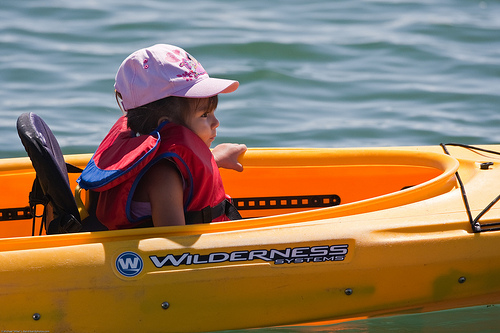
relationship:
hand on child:
[212, 144, 252, 173] [68, 45, 240, 230]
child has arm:
[79, 39, 249, 228] [140, 150, 196, 232]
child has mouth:
[79, 39, 249, 228] [207, 132, 217, 143]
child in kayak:
[79, 39, 256, 220] [2, 120, 499, 330]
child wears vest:
[79, 39, 249, 228] [73, 122, 250, 234]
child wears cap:
[79, 39, 249, 228] [112, 44, 240, 113]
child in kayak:
[79, 39, 249, 228] [288, 146, 489, 296]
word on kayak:
[148, 242, 352, 264] [2, 120, 499, 330]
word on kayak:
[272, 256, 344, 263] [2, 120, 499, 330]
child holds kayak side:
[79, 39, 249, 228] [212, 144, 444, 166]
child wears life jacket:
[79, 39, 249, 228] [75, 126, 230, 213]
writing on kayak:
[145, 245, 350, 267] [0, 141, 499, 331]